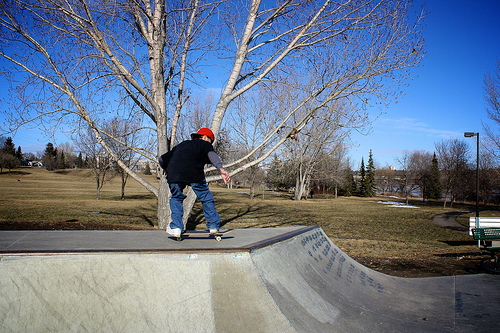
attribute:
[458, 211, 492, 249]
bench — white, park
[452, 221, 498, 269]
bench — park, green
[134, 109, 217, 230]
man — young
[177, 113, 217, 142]
cap — red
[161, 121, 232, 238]
man — young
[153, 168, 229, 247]
jeans — blue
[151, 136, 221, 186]
sweater — blue, gray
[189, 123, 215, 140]
cap — red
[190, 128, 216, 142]
cap — red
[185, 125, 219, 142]
cap — red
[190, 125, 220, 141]
cap — red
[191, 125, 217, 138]
hat — red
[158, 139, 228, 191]
shirt — black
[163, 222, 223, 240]
tennis shoes — white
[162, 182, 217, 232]
jeans — blue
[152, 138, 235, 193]
shirt — long sleeved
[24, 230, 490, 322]
skateboarding ramp — concrete